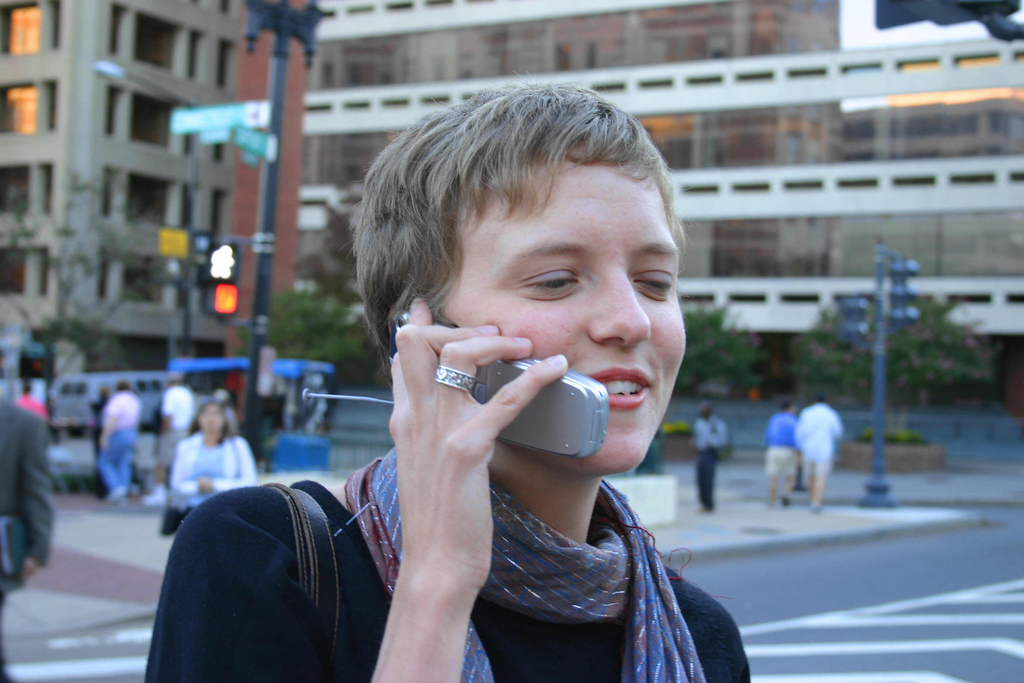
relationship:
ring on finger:
[427, 355, 475, 394] [466, 346, 564, 420]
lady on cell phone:
[129, 72, 752, 669] [386, 315, 621, 463]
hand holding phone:
[373, 296, 562, 560] [449, 335, 622, 463]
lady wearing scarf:
[129, 72, 752, 669] [343, 420, 726, 671]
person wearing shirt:
[762, 394, 810, 518] [764, 411, 808, 448]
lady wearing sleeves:
[129, 73, 750, 683] [136, 482, 337, 643]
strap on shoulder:
[274, 466, 363, 652] [143, 470, 370, 589]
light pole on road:
[251, 19, 340, 447] [0, 514, 1024, 683]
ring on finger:
[427, 355, 474, 394] [434, 328, 530, 387]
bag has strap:
[259, 470, 389, 678] [266, 470, 355, 611]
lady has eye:
[129, 73, 750, 683] [516, 265, 579, 302]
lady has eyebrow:
[129, 73, 750, 683] [497, 235, 593, 268]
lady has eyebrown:
[129, 73, 750, 683] [624, 231, 683, 271]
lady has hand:
[129, 73, 750, 683] [359, 295, 574, 630]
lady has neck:
[129, 73, 750, 683] [493, 466, 608, 540]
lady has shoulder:
[129, 73, 750, 683] [657, 555, 772, 674]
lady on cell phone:
[129, 73, 750, 683] [456, 354, 619, 465]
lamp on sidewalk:
[851, 246, 925, 502] [843, 466, 1021, 510]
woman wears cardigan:
[154, 388, 261, 510] [162, 432, 266, 495]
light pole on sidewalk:
[241, 19, 300, 448] [248, 443, 355, 476]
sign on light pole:
[199, 235, 251, 279] [241, 19, 300, 448]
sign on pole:
[225, 116, 284, 164] [266, 8, 325, 343]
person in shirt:
[783, 394, 870, 544] [794, 403, 847, 492]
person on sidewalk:
[783, 394, 870, 544] [796, 493, 866, 569]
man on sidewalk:
[684, 403, 737, 535] [668, 489, 790, 556]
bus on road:
[70, 340, 185, 427] [152, 431, 341, 484]